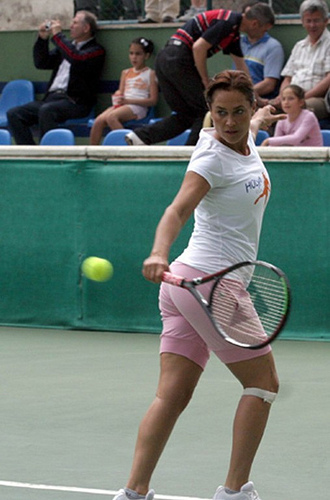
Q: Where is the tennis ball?
A: In the air.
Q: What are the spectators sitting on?
A: Blue seats.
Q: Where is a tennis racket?
A: In woman's hand.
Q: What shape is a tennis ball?
A: Round.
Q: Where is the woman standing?
A: On a tennis court.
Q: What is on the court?
A: A white line.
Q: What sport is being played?
A: Tennis.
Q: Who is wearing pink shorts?
A: Tennis player.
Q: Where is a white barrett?
A: In young girl's hair.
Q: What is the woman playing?
A: Tennis.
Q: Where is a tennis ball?
A: In the air.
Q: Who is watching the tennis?
A: Spectators.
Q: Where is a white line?
A: On the court.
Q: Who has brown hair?
A: The player.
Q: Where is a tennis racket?
A: In woman's hand.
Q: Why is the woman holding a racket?
A: To hit the ball.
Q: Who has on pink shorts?
A: Tennis player.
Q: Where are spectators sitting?
A: On blue chairs.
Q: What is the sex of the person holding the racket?
A: Female.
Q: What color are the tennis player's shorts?
A: Pink.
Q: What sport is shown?
A: Tennis.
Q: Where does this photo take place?
A: On a tennis court.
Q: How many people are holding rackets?
A: One.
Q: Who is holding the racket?
A: The woman in pink shorts.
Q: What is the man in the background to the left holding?
A: A digital camera.